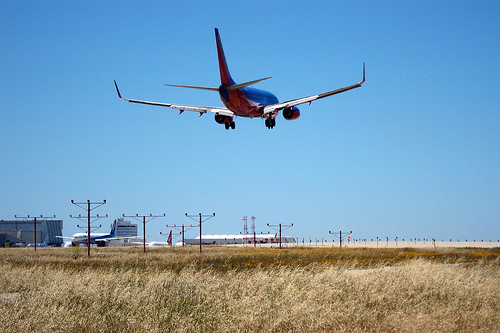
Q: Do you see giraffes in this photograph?
A: No, there are no giraffes.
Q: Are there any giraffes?
A: No, there are no giraffes.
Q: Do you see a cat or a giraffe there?
A: No, there are no giraffes or cats.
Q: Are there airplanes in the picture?
A: Yes, there is an airplane.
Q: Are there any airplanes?
A: Yes, there is an airplane.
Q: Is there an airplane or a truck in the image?
A: Yes, there is an airplane.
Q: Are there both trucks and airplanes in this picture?
A: No, there is an airplane but no trucks.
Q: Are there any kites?
A: No, there are no kites.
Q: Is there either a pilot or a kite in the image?
A: No, there are no kites or pilots.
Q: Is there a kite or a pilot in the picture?
A: No, there are no kites or pilots.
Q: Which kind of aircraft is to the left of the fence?
A: The aircraft is an airplane.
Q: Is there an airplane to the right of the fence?
A: No, the airplane is to the left of the fence.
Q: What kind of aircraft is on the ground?
A: The aircraft is an airplane.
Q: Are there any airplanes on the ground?
A: Yes, there is an airplane on the ground.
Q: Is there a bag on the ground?
A: No, there is an airplane on the ground.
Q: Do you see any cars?
A: No, there are no cars.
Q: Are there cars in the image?
A: No, there are no cars.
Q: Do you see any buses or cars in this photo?
A: No, there are no cars or buses.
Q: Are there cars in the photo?
A: No, there are no cars.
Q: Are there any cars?
A: No, there are no cars.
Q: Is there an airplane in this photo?
A: Yes, there is an airplane.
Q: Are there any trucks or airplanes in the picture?
A: Yes, there is an airplane.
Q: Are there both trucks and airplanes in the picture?
A: No, there is an airplane but no trucks.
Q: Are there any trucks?
A: No, there are no trucks.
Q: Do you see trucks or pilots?
A: No, there are no trucks or pilots.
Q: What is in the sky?
A: The plane is in the sky.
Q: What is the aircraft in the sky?
A: The aircraft is an airplane.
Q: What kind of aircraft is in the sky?
A: The aircraft is an airplane.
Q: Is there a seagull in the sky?
A: No, there is an airplane in the sky.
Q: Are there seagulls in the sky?
A: No, there is an airplane in the sky.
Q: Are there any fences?
A: Yes, there is a fence.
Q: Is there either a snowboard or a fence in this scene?
A: Yes, there is a fence.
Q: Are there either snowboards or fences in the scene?
A: Yes, there is a fence.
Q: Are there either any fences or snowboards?
A: Yes, there is a fence.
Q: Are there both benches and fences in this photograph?
A: No, there is a fence but no benches.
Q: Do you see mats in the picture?
A: No, there are no mats.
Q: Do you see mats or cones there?
A: No, there are no mats or cones.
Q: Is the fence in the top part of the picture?
A: No, the fence is in the bottom of the image.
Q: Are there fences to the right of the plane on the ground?
A: Yes, there is a fence to the right of the plane.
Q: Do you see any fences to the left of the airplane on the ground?
A: No, the fence is to the right of the plane.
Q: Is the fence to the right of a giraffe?
A: No, the fence is to the right of the airplane.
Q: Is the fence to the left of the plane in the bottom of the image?
A: No, the fence is to the right of the plane.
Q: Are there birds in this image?
A: No, there are no birds.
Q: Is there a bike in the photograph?
A: No, there are no bikes.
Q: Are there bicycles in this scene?
A: No, there are no bicycles.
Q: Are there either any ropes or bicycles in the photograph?
A: No, there are no bicycles or ropes.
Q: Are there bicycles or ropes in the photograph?
A: No, there are no bicycles or ropes.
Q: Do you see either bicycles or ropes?
A: No, there are no bicycles or ropes.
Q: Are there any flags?
A: No, there are no flags.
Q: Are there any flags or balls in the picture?
A: No, there are no flags or balls.